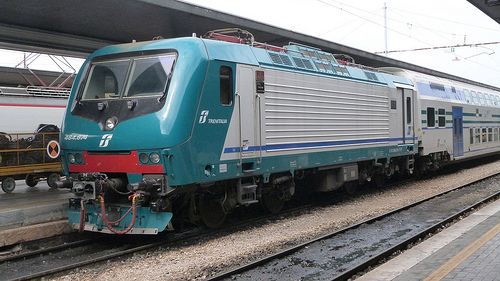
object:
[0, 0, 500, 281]
day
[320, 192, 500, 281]
tracks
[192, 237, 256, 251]
gravel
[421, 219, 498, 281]
line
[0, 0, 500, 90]
roof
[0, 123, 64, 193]
vehicle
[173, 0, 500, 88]
sky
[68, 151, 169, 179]
bumper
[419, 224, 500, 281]
stripe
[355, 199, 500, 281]
ground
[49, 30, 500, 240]
railing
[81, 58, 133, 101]
windows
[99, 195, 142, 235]
wires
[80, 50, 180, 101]
windshield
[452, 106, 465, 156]
door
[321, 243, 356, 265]
water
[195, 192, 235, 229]
wheels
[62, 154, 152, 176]
panel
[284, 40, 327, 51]
handles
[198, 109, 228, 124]
lettering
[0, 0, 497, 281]
station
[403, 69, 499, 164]
car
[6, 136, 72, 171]
cart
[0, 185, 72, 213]
platform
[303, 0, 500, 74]
wires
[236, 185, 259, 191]
steps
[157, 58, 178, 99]
wiper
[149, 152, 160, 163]
headlights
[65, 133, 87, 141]
number